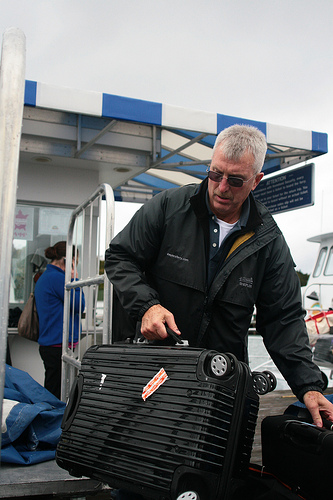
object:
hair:
[212, 121, 269, 174]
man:
[103, 121, 333, 428]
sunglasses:
[205, 164, 259, 189]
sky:
[38, 41, 333, 91]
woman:
[33, 240, 88, 400]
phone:
[61, 255, 77, 275]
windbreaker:
[104, 176, 330, 404]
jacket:
[34, 260, 85, 350]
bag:
[18, 266, 42, 348]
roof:
[25, 77, 329, 154]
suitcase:
[52, 338, 278, 500]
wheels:
[206, 350, 236, 378]